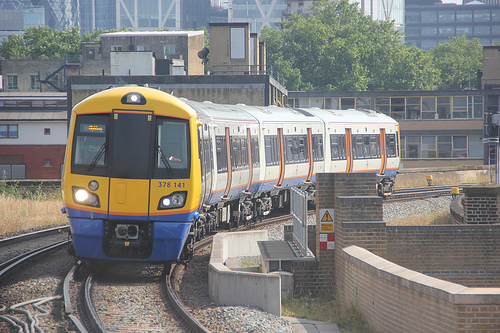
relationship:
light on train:
[71, 182, 102, 209] [61, 85, 409, 269]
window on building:
[403, 95, 418, 124] [66, 76, 493, 164]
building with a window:
[66, 76, 493, 164] [403, 95, 418, 124]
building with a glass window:
[66, 76, 493, 164] [403, 95, 418, 124]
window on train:
[403, 95, 418, 124] [61, 85, 409, 269]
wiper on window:
[87, 138, 112, 173] [403, 95, 418, 124]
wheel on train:
[194, 217, 205, 239] [61, 85, 409, 269]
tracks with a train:
[62, 259, 210, 331] [61, 85, 409, 269]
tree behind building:
[272, 1, 399, 98] [66, 76, 493, 164]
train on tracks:
[61, 85, 409, 269] [62, 259, 210, 331]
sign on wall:
[316, 210, 337, 251] [316, 165, 498, 332]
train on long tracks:
[61, 85, 409, 269] [62, 259, 210, 331]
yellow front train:
[62, 82, 199, 215] [61, 85, 409, 269]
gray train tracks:
[185, 97, 398, 172] [62, 259, 210, 331]